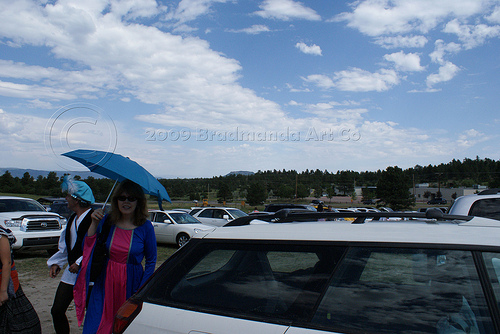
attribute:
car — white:
[120, 215, 497, 332]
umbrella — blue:
[60, 145, 171, 208]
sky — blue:
[2, 2, 498, 161]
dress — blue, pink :
[70, 207, 158, 332]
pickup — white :
[1, 177, 58, 254]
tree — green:
[18, 170, 34, 182]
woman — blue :
[77, 178, 157, 333]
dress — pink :
[75, 215, 156, 332]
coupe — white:
[150, 208, 212, 245]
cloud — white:
[332, 70, 389, 93]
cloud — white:
[307, 72, 331, 92]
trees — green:
[250, 143, 480, 184]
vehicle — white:
[108, 208, 499, 333]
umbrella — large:
[53, 136, 185, 209]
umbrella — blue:
[61, 146, 176, 231]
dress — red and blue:
[88, 257, 122, 334]